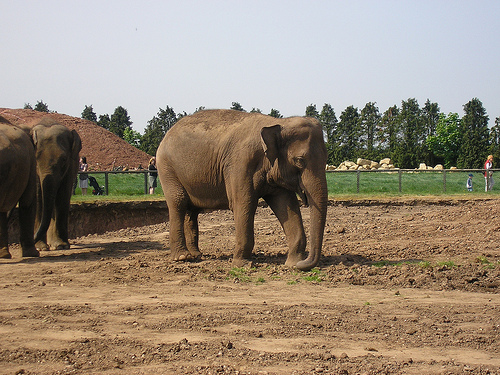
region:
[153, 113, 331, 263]
an elephant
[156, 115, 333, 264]
elephants is grey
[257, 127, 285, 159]
the elephants ear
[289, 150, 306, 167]
the elephants eye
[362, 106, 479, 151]
the trees are tall and green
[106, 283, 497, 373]
the dirt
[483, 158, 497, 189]
a person standing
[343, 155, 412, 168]
rocks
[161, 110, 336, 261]
the elephant is standing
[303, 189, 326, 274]
the elephants trunk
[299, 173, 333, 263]
the trunk of an elephant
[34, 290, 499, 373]
the dirt on the ground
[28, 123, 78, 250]
an elephant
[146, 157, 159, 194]
a person standing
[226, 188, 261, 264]
the elephants leg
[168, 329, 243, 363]
small rocks in the dirt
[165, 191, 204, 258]
the elephants back legs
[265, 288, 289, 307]
part of a ground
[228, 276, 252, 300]
part of a ground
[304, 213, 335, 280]
part of a trunk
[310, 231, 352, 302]
part of a trubk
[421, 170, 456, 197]
part of a fennce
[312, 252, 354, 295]
part of a ground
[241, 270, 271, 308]
part of a ground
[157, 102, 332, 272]
A grey elephant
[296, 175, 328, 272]
A trunk of an elephant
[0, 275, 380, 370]
Dirt and rocks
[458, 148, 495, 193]
A kid and an adult watching the elephants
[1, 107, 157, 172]
a big mound of dirt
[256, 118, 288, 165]
An elephants big floppy ear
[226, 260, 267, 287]
a patch of green grass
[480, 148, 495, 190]
a woman in a red jacket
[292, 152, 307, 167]
an elephants right eye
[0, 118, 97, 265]
Two elephants standing together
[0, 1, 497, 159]
The sky is blue.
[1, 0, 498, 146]
The sky has clouds in it.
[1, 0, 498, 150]
The clouds are blue and white.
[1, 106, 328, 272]
The elephants are brown.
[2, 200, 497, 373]
The ground is dirt.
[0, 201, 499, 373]
The ground is brown.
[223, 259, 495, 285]
Grass is in the dirt.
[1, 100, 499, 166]
The trees are green.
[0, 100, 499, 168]
The trees have leaves.